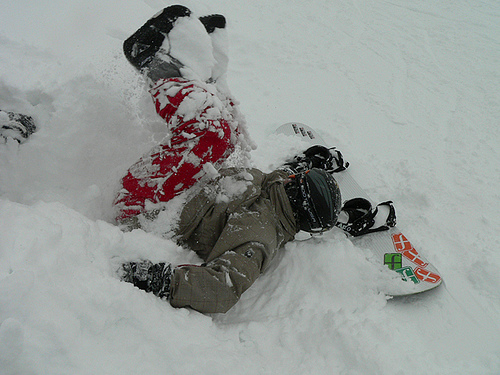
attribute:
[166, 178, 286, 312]
jacket — gray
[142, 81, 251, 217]
pants — red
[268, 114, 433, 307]
snowboard — white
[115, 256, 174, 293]
glove — black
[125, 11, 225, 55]
shoes — black, back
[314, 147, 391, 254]
strap — black